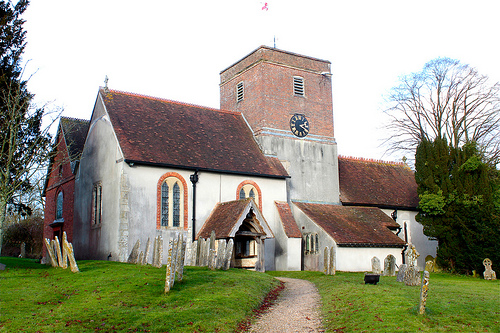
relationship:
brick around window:
[278, 201, 286, 208] [147, 169, 191, 234]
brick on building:
[278, 201, 286, 208] [75, 73, 306, 275]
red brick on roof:
[101, 87, 285, 182] [98, 87, 290, 178]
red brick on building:
[101, 87, 285, 182] [76, 87, 298, 267]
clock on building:
[290, 112, 309, 137] [52, 47, 434, 271]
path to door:
[237, 269, 326, 331] [239, 226, 265, 268]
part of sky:
[98, 6, 148, 43] [415, 3, 491, 51]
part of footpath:
[264, 306, 300, 328] [242, 274, 324, 331]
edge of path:
[301, 302, 325, 328] [237, 273, 326, 331]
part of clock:
[288, 121, 306, 139] [288, 113, 308, 138]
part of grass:
[95, 280, 175, 330] [366, 305, 390, 325]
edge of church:
[75, 168, 117, 223] [35, 33, 444, 272]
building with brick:
[52, 47, 434, 271] [221, 44, 335, 138]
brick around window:
[179, 180, 186, 186] [154, 170, 189, 226]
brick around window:
[179, 194, 191, 201] [154, 170, 189, 226]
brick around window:
[180, 219, 191, 230] [154, 170, 189, 226]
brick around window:
[149, 217, 165, 228] [154, 170, 189, 226]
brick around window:
[157, 189, 164, 196] [154, 170, 189, 226]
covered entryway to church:
[198, 198, 275, 269] [39, 44, 444, 272]